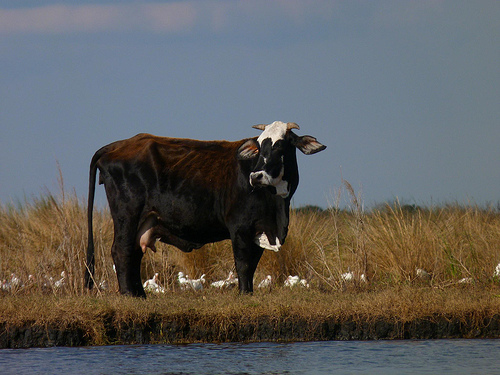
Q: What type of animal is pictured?
A: Cow.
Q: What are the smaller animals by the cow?
A: Birds.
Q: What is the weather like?
A: Sunny.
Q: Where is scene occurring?
A: Field by river.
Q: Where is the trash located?
A: Behind cow in field.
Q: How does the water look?
A: Calm and green.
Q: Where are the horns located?
A: On top of cows head.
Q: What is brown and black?
A: The cow.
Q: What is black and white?
A: The cow's head.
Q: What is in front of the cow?
A: A body of water.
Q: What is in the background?
A: Grass.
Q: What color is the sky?
A: Blue.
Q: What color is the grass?
A: Brown.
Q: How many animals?
A: One.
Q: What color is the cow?
A: Black.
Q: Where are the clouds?
A: Sky.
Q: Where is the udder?
A: On cow.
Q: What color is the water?
A: Silver.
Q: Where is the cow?
A: In grass.